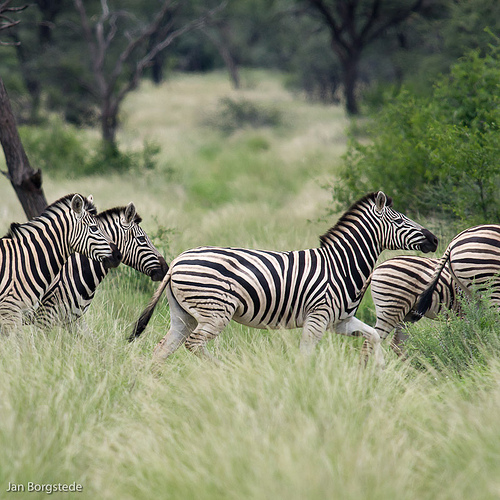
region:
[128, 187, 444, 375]
a zebra walking on the grass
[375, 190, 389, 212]
the ear of a zebra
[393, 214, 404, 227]
the eye of a zebra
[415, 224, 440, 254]
the mouth of a zebra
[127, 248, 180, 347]
the tail of a zebra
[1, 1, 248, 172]
a blurry tree in the background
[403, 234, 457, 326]
the tail of a zebra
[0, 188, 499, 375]
a pack of zebras on the grass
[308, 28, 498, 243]
a green shrub in the background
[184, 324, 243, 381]
the leg of a zebra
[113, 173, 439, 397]
this is a zebra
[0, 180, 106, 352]
this is a zebra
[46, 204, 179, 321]
this is a zebra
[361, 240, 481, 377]
this is a zebra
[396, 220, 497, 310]
this is a zebra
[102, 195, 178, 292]
the head of a zebra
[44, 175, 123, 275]
the head of a zebra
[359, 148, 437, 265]
the head of a zebra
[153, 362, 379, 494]
this is long grass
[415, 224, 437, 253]
nose of the horse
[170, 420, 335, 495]
grass on the ground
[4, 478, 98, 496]
watermark for the photographer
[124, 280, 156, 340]
tail of the zebra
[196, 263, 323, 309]
stripes on the zebra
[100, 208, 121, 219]
mane of the zebra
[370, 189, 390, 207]
ear of the zebra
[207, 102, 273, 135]
bush in the back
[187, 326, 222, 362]
leg of the zebra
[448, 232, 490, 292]
back of the zebra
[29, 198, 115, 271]
A black abd white zebra's head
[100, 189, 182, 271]
A black abd white zebra's head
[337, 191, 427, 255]
A black abd white zebra's head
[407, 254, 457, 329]
A black abd white zebra's tail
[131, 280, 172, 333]
A black abd white zebra's tail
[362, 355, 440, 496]
Tall brown and green grass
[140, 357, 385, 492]
Tall brown and green grass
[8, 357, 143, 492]
Tall brown and green grass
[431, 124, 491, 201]
A short green tree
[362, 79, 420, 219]
A short green tree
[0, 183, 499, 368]
A herd of Zebras in high grass